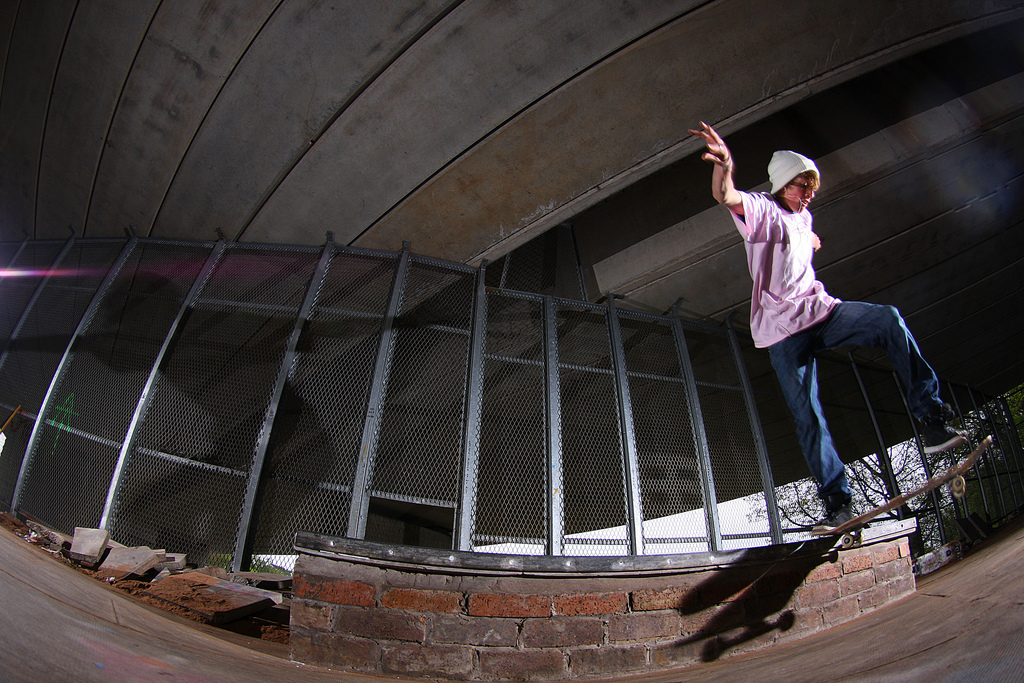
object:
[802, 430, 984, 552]
skateboard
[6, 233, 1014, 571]
fence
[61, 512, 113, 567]
piece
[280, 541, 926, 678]
wall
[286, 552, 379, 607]
brick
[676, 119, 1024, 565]
kid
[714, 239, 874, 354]
shirt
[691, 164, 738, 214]
arm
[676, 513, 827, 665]
shadow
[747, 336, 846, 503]
leg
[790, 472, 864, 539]
shoes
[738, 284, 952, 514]
jeans